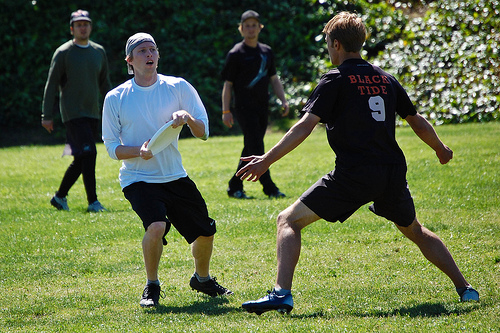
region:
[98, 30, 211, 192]
Man is holding the frisbee in hand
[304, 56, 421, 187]
Person is running defense on player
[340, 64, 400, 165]
Team name is on the back of shirt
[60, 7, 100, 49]
Player is wearing a hat in the back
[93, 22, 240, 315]
man holding a white frisbee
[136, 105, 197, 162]
hands holding a frisbee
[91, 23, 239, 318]
man wearing a cap backwards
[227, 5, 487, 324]
man is number 9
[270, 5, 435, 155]
man is number 9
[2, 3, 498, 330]
man in a green field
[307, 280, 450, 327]
shadow on the green grass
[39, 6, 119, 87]
man wearing a blue cup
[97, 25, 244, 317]
the man is bend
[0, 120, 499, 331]
a field of green grass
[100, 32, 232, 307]
a man holding a frisbee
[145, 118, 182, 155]
white frisbee held by the man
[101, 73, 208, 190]
the man's white shirt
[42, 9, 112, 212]
a man walking on the field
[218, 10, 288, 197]
a man walking on the field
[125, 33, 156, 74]
baseball cap worn by a man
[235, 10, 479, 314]
a man playing on a field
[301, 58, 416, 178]
a man's black shirt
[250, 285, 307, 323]
the man's left shoe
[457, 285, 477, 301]
the man's right shoe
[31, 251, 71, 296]
the green grass on the ground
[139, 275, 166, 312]
the other man's left foot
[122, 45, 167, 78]
the man's head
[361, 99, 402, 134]
the number 9 on his jersey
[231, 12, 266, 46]
the man in the background head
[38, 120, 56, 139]
the man's hand in the distance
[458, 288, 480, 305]
shoe on man's foot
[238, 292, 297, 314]
shoe on man's foot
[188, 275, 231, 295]
shoe on man's foot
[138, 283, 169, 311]
shoe on man's foot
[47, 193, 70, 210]
shoe on man's foot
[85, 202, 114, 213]
shoe on man's foot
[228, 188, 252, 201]
shoe on man's foot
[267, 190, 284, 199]
shoe on man's foot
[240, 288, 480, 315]
shoes on man's feet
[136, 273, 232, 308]
shoes on man's feet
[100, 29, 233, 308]
Man holding a Frisbee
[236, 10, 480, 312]
Man with arms extended to blocl throw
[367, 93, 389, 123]
The number 9 on man's t-shirt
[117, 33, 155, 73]
Bandana on man's head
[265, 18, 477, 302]
A person is playing.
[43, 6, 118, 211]
A person walking on the grass.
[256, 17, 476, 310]
A person walking on the grass.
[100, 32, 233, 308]
Man holding a frisbee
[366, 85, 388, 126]
The number 9 on the man's shirt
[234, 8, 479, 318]
Man standing with arms outstretched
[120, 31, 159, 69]
Kerchief on man's head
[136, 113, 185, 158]
White Frisbee in man's hands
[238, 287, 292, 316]
Man's cleated shoe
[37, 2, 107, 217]
Man walking in the grass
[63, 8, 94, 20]
Baseball cap on man's head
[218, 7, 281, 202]
Man walking in the grass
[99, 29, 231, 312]
Man holding a Frisbee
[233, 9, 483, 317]
Man with arm's outspread trying to block the Frisbee holder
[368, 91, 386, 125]
Number 9 on the man's shirt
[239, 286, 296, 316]
Athletic shoe with cleats on the man's foot